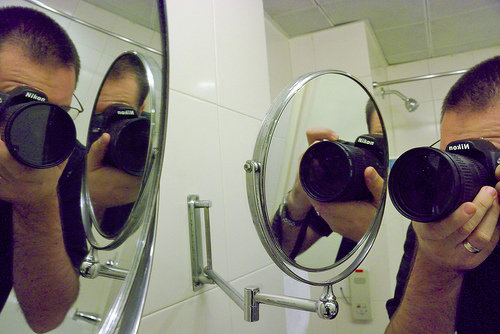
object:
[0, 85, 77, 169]
camera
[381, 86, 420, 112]
shower rod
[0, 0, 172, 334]
mirror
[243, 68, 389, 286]
mirror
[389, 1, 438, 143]
wall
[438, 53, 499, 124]
hair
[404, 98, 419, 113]
shower head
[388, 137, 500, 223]
camera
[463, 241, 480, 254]
ring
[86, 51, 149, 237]
man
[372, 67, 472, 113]
curtain rod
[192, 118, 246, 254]
tile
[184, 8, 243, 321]
wall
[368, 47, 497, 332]
man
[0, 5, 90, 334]
man